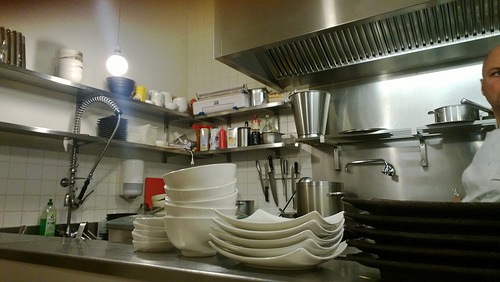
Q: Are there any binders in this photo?
A: No, there are no binders.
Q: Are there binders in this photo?
A: No, there are no binders.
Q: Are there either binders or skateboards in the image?
A: No, there are no binders or skateboards.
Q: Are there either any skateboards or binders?
A: No, there are no binders or skateboards.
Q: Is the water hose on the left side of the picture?
A: Yes, the water hose is on the left of the image.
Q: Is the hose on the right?
A: No, the hose is on the left of the image.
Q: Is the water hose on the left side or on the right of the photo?
A: The water hose is on the left of the image.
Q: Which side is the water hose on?
A: The water hose is on the left of the image.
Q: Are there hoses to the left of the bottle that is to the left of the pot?
A: Yes, there is a hose to the left of the bottle.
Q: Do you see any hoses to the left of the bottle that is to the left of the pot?
A: Yes, there is a hose to the left of the bottle.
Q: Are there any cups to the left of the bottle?
A: No, there is a hose to the left of the bottle.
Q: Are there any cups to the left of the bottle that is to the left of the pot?
A: No, there is a hose to the left of the bottle.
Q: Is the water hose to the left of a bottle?
A: Yes, the water hose is to the left of a bottle.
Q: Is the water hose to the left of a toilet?
A: No, the water hose is to the left of a bottle.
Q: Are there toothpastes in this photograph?
A: No, there are no toothpastes.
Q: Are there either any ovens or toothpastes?
A: No, there are no toothpastes or ovens.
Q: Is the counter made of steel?
A: Yes, the counter is made of steel.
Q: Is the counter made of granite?
A: No, the counter is made of steel.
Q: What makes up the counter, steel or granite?
A: The counter is made of steel.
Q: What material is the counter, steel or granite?
A: The counter is made of steel.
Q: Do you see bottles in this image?
A: Yes, there is a bottle.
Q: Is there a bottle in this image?
A: Yes, there is a bottle.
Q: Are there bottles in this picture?
A: Yes, there is a bottle.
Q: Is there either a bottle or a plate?
A: Yes, there is a bottle.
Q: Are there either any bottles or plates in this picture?
A: Yes, there is a bottle.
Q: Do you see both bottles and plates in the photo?
A: Yes, there are both a bottle and a plate.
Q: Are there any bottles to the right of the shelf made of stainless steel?
A: Yes, there is a bottle to the right of the shelf.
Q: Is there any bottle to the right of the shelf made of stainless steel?
A: Yes, there is a bottle to the right of the shelf.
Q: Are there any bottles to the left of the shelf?
A: No, the bottle is to the right of the shelf.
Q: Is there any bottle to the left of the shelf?
A: No, the bottle is to the right of the shelf.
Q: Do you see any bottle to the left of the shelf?
A: No, the bottle is to the right of the shelf.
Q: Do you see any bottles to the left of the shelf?
A: No, the bottle is to the right of the shelf.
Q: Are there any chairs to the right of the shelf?
A: No, there is a bottle to the right of the shelf.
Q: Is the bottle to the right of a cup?
A: No, the bottle is to the right of a shelf.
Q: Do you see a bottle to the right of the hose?
A: Yes, there is a bottle to the right of the hose.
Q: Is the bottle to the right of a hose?
A: Yes, the bottle is to the right of a hose.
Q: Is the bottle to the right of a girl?
A: No, the bottle is to the right of a hose.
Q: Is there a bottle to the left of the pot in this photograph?
A: Yes, there is a bottle to the left of the pot.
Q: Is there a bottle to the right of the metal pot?
A: No, the bottle is to the left of the pot.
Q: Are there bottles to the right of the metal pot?
A: No, the bottle is to the left of the pot.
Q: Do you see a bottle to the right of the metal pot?
A: No, the bottle is to the left of the pot.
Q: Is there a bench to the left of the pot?
A: No, there is a bottle to the left of the pot.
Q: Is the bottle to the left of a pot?
A: Yes, the bottle is to the left of a pot.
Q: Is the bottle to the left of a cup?
A: No, the bottle is to the left of a pot.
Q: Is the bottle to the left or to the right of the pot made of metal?
A: The bottle is to the left of the pot.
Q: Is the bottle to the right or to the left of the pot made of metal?
A: The bottle is to the left of the pot.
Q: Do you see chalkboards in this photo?
A: No, there are no chalkboards.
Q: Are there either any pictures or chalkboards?
A: No, there are no chalkboards or pictures.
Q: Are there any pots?
A: Yes, there is a pot.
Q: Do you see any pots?
A: Yes, there is a pot.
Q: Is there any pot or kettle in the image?
A: Yes, there is a pot.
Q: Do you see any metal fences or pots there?
A: Yes, there is a metal pot.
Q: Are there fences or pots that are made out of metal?
A: Yes, the pot is made of metal.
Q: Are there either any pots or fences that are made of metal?
A: Yes, the pot is made of metal.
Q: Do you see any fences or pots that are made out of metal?
A: Yes, the pot is made of metal.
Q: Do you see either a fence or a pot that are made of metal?
A: Yes, the pot is made of metal.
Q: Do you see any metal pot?
A: Yes, there is a pot that is made of metal.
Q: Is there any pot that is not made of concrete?
A: Yes, there is a pot that is made of metal.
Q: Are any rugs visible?
A: No, there are no rugs.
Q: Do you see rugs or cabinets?
A: No, there are no rugs or cabinets.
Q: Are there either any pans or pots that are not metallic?
A: No, there is a pot but it is metallic.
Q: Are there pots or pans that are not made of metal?
A: No, there is a pot but it is made of metal.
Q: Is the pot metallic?
A: Yes, the pot is metallic.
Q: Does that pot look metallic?
A: Yes, the pot is metallic.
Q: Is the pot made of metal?
A: Yes, the pot is made of metal.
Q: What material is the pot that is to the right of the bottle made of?
A: The pot is made of metal.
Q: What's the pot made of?
A: The pot is made of metal.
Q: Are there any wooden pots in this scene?
A: No, there is a pot but it is metallic.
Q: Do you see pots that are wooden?
A: No, there is a pot but it is metallic.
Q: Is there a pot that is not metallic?
A: No, there is a pot but it is metallic.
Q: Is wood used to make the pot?
A: No, the pot is made of metal.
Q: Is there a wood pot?
A: No, there is a pot but it is made of metal.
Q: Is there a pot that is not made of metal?
A: No, there is a pot but it is made of metal.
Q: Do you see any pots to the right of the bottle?
A: Yes, there is a pot to the right of the bottle.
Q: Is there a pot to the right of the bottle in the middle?
A: Yes, there is a pot to the right of the bottle.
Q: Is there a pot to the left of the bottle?
A: No, the pot is to the right of the bottle.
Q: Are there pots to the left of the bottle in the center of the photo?
A: No, the pot is to the right of the bottle.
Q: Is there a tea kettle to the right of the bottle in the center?
A: No, there is a pot to the right of the bottle.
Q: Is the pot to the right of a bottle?
A: Yes, the pot is to the right of a bottle.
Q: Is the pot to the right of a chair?
A: No, the pot is to the right of a bottle.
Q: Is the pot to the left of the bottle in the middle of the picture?
A: No, the pot is to the right of the bottle.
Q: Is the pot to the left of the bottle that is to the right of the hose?
A: No, the pot is to the right of the bottle.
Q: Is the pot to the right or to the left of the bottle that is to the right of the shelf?
A: The pot is to the right of the bottle.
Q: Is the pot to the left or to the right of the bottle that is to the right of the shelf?
A: The pot is to the right of the bottle.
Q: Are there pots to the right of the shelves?
A: Yes, there is a pot to the right of the shelves.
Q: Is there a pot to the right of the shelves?
A: Yes, there is a pot to the right of the shelves.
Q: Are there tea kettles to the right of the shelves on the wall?
A: No, there is a pot to the right of the shelves.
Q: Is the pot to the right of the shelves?
A: Yes, the pot is to the right of the shelves.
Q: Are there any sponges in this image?
A: No, there are no sponges.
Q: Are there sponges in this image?
A: No, there are no sponges.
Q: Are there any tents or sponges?
A: No, there are no sponges or tents.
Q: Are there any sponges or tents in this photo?
A: No, there are no sponges or tents.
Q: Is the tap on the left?
A: Yes, the tap is on the left of the image.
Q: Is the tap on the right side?
A: No, the tap is on the left of the image.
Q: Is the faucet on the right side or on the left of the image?
A: The faucet is on the left of the image.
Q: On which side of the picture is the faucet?
A: The faucet is on the left of the image.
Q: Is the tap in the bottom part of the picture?
A: Yes, the tap is in the bottom of the image.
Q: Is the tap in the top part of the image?
A: No, the tap is in the bottom of the image.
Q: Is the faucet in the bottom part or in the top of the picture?
A: The faucet is in the bottom of the image.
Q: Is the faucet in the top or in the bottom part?
A: The faucet is in the bottom of the image.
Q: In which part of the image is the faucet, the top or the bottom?
A: The faucet is in the bottom of the image.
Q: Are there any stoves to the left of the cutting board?
A: No, there is a faucet to the left of the cutting board.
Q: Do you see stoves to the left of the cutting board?
A: No, there is a faucet to the left of the cutting board.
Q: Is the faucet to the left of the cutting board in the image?
A: Yes, the faucet is to the left of the cutting board.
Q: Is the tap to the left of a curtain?
A: No, the tap is to the left of the cutting board.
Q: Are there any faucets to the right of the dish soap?
A: Yes, there is a faucet to the right of the dish soap.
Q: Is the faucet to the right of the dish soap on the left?
A: Yes, the faucet is to the right of the dish soap.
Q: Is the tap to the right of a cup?
A: No, the tap is to the right of the dish soap.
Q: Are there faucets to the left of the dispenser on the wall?
A: Yes, there is a faucet to the left of the dispenser.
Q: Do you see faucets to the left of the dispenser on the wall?
A: Yes, there is a faucet to the left of the dispenser.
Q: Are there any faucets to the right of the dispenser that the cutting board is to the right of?
A: No, the faucet is to the left of the dispenser.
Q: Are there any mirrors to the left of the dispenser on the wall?
A: No, there is a faucet to the left of the dispenser.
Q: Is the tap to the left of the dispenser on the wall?
A: Yes, the tap is to the left of the dispenser.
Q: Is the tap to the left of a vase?
A: No, the tap is to the left of the dispenser.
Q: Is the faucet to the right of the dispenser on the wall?
A: No, the faucet is to the left of the dispenser.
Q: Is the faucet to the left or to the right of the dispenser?
A: The faucet is to the left of the dispenser.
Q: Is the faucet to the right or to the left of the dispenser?
A: The faucet is to the left of the dispenser.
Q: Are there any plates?
A: Yes, there is a plate.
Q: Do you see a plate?
A: Yes, there is a plate.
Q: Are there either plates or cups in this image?
A: Yes, there is a plate.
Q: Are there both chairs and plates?
A: No, there is a plate but no chairs.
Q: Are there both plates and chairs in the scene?
A: No, there is a plate but no chairs.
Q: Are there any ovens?
A: No, there are no ovens.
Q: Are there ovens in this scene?
A: No, there are no ovens.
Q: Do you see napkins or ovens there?
A: No, there are no ovens or napkins.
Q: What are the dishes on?
A: The dishes are on the counter.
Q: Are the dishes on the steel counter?
A: Yes, the dishes are on the counter.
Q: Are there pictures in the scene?
A: No, there are no pictures.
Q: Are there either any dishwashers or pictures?
A: No, there are no pictures or dishwashers.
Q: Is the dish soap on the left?
A: Yes, the dish soap is on the left of the image.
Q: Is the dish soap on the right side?
A: No, the dish soap is on the left of the image.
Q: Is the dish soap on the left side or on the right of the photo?
A: The dish soap is on the left of the image.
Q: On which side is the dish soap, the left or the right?
A: The dish soap is on the left of the image.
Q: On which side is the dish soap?
A: The dish soap is on the left of the image.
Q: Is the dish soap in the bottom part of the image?
A: Yes, the dish soap is in the bottom of the image.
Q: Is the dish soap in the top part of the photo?
A: No, the dish soap is in the bottom of the image.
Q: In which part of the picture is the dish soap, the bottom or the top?
A: The dish soap is in the bottom of the image.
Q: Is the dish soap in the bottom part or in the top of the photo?
A: The dish soap is in the bottom of the image.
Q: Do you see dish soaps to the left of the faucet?
A: Yes, there is a dish soap to the left of the faucet.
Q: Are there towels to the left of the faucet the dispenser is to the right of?
A: No, there is a dish soap to the left of the tap.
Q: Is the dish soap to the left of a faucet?
A: Yes, the dish soap is to the left of a faucet.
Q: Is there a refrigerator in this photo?
A: No, there are no refrigerators.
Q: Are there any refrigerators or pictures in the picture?
A: No, there are no refrigerators or pictures.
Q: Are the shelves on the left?
A: Yes, the shelves are on the left of the image.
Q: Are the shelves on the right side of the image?
A: No, the shelves are on the left of the image.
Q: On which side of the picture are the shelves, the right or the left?
A: The shelves are on the left of the image.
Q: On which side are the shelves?
A: The shelves are on the left of the image.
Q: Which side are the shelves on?
A: The shelves are on the left of the image.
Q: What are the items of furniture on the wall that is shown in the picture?
A: The pieces of furniture are shelves.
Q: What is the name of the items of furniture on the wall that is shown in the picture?
A: The pieces of furniture are shelves.